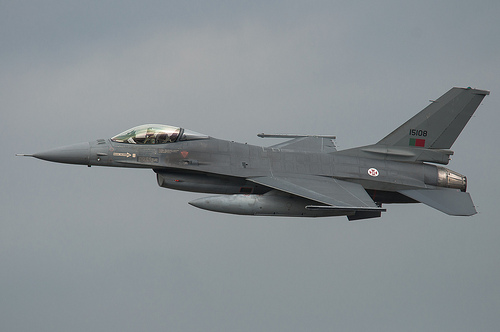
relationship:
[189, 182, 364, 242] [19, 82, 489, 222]
missile on aircraft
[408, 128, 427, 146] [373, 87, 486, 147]
markings on tail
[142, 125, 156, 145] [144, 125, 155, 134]
pilot wearing a helmet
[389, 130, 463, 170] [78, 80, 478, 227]
numbers on tail of aircraft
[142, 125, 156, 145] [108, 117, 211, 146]
pilot through glass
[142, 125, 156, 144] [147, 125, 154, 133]
pilot wearing helmet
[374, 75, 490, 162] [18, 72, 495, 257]
tail of airplane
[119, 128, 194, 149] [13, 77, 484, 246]
cockpit of airplane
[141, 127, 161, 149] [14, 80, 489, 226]
person flying airplane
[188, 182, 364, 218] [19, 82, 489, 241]
missile on aircraft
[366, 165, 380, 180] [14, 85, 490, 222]
symbol on aircraft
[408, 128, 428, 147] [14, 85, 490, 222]
markings on aircraft